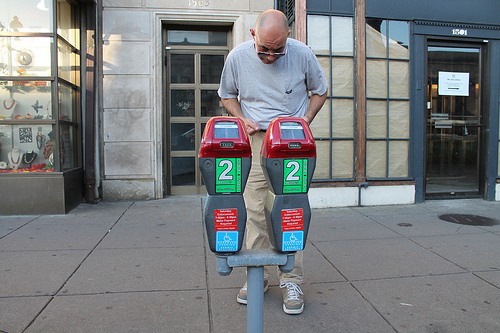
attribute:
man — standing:
[239, 24, 311, 101]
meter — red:
[202, 118, 261, 241]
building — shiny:
[82, 19, 167, 115]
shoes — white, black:
[287, 276, 309, 309]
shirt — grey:
[265, 60, 330, 106]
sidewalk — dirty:
[101, 221, 167, 295]